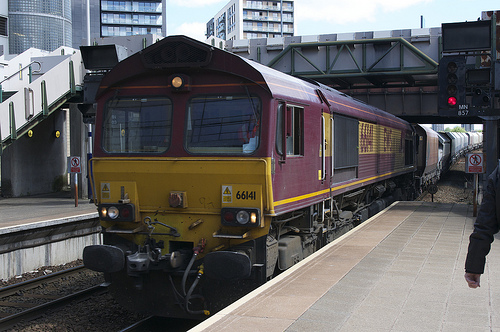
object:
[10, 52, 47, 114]
strairs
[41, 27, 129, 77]
walkway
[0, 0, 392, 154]
building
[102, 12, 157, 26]
window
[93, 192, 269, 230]
headlights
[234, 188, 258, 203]
numbers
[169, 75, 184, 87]
light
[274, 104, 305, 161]
window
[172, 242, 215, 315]
cords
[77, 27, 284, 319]
front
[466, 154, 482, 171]
street sign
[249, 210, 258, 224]
light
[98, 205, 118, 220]
light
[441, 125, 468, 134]
tree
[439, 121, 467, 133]
leaves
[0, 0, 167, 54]
building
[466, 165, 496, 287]
sleeve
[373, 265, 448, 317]
stone tiles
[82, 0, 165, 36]
windows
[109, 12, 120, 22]
window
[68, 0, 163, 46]
building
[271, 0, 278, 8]
window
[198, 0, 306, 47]
building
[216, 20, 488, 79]
walkway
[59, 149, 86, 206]
sign post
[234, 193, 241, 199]
number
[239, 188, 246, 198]
number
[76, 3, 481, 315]
train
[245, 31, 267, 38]
window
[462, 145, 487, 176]
warning sign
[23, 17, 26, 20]
window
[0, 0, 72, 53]
building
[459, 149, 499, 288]
person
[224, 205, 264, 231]
headlight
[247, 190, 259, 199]
4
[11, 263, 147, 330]
track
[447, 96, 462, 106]
light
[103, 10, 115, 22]
window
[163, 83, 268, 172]
windshield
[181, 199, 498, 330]
train platform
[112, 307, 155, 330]
train track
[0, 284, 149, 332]
train track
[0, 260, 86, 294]
train track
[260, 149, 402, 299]
broadsection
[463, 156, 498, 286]
arm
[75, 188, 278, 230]
light